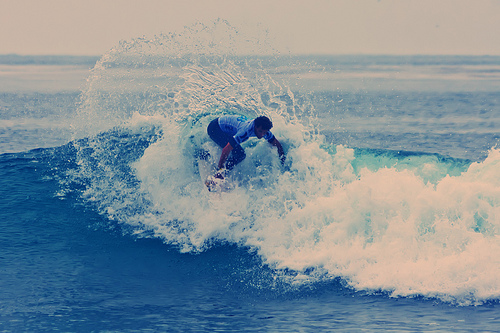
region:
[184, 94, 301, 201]
surfer on board in water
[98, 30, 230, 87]
splash of water from ocean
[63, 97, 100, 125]
splash of water from ocean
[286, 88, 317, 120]
splash of water from ocean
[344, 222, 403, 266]
water from ocean waves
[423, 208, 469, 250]
water from ocean waves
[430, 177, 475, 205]
water from ocean waves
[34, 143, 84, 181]
wave coming up behind surfer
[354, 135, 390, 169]
wave coming up behind surfer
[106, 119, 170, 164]
wave coming up behind surfer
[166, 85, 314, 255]
the man in the ocean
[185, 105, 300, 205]
the man on the surfboard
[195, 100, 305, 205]
the man is wet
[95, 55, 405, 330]
the water is splashing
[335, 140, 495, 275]
the wave in the ocean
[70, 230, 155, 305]
the pristine blue water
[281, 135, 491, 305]
the wave is crashing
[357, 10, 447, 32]
the clear blue sky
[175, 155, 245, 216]
the surfboard is white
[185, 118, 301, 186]
a man surfing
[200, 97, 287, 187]
the man is surfing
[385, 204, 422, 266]
the water is white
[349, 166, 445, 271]
the wave is crashing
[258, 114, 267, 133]
the hair is black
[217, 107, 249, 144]
the shirt is white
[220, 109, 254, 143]
the surfer is wearing a shirt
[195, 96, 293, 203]
the surfer is leaning over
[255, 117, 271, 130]
the surfer has hair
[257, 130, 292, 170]
the arm is in the water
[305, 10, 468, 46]
the sky is white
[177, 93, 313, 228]
the man on a surfboard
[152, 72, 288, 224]
the man is surfing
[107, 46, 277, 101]
the water is splashing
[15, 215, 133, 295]
the pristine blue ocean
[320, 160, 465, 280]
the wave is foaming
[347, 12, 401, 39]
the sky is gray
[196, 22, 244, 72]
water of ocean splashing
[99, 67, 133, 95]
water of ocean splashing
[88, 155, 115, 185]
water of ocean splashing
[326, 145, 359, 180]
water of ocean splashing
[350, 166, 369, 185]
water of ocean splashing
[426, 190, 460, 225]
water of ocean splashing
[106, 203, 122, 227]
water of ocean splashing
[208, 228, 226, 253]
water of ocean splashing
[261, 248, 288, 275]
water of ocean splashing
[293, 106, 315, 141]
water of ocean splashing